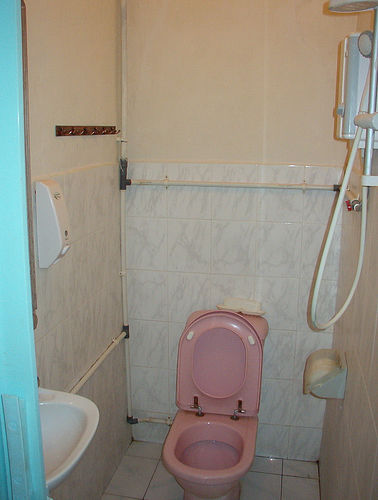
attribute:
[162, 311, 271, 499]
comode — pink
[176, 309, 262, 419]
seat — up, pink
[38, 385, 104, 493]
sink — white, ceramic, bathroom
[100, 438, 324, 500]
tile — white, tiled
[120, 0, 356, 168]
wall — white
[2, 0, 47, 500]
door — light blue, blue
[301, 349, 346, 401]
paper holder — ceramic, covered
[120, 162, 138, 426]
connectors — black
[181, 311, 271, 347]
water tank — pink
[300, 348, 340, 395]
toiler paper — white